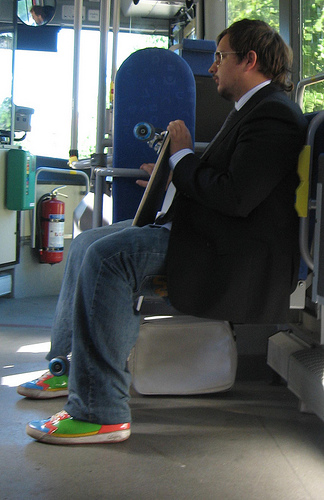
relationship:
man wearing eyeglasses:
[193, 29, 270, 117] [201, 45, 246, 64]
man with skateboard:
[193, 29, 270, 117] [121, 109, 185, 241]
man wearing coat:
[193, 29, 270, 117] [190, 99, 277, 282]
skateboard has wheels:
[121, 109, 185, 241] [122, 111, 158, 149]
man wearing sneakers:
[193, 29, 270, 117] [18, 371, 135, 455]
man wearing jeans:
[193, 29, 270, 117] [56, 218, 165, 408]